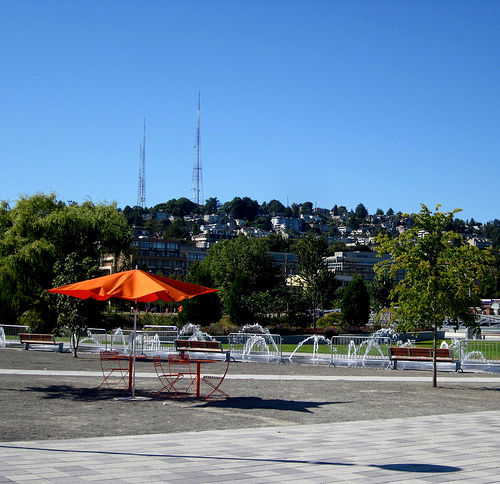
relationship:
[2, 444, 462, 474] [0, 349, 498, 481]
shadow on ground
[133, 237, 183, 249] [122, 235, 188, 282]
windows in building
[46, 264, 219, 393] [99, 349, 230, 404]
orange umbrella shading table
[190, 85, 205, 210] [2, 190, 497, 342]
antenna on hill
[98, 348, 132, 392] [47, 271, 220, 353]
chair underneath umbrella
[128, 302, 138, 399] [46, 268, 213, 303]
pole of umbrella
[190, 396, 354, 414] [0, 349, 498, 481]
shadow on ground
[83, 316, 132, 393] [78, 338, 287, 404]
chair pushed into table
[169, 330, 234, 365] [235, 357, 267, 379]
brown bench on concrete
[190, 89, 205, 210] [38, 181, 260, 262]
antenna over tree tops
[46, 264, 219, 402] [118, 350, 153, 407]
orange umbrella on stand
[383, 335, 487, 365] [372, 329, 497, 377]
back of bench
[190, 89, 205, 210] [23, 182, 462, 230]
antenna on horizon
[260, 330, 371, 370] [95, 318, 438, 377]
water of fountain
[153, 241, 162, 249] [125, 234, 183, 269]
window on side of building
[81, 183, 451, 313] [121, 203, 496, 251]
hilltop has houses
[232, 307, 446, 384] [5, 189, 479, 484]
fountains in park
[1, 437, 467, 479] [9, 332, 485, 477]
shadows on cement